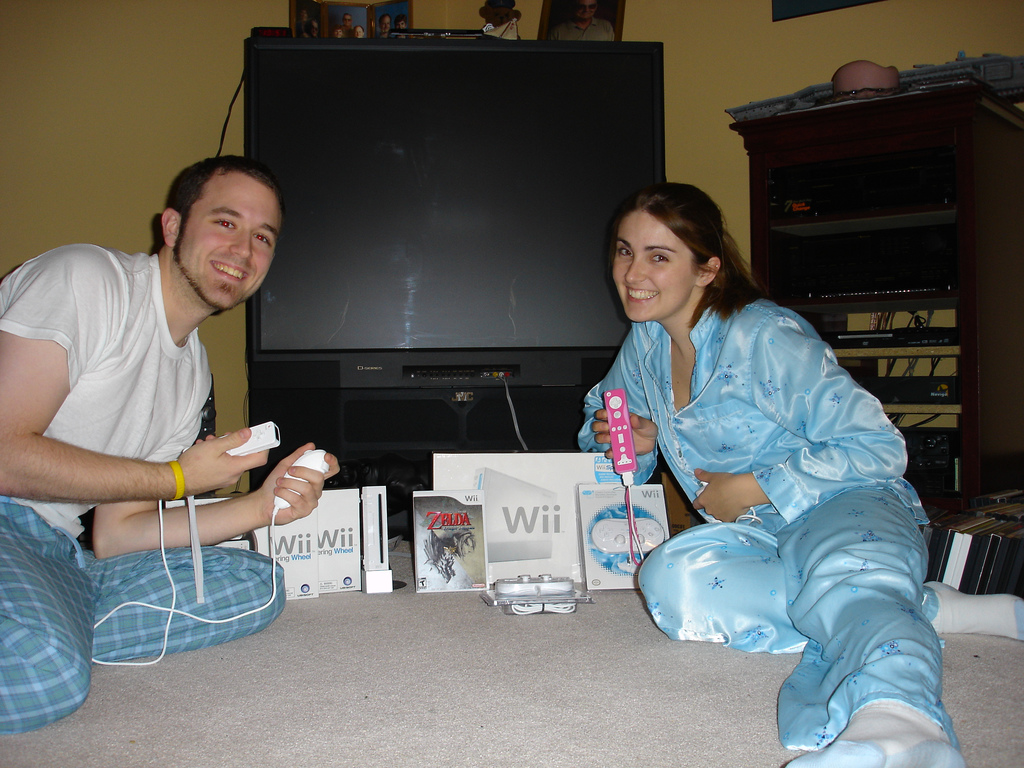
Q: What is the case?
A: Zelda game.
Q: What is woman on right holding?
A: Pink controller.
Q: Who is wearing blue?
A: Woman with pink controller.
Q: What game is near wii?
A: Zelda.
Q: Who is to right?
A: Woman in blue.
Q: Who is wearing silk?
A: Woman to the right.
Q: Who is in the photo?
A: Young couple.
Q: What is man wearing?
A: Blue flannel pants.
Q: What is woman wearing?
A: Blue 2 piece pajamas.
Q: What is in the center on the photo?
A: Zelda game.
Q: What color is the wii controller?
A: Pink and white.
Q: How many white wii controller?
A: Two.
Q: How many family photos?
A: Four.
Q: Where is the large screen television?
A: Behind the couple.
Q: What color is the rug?
A: Gray.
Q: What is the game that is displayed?
A: Zelda.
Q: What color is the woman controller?
A: Pink.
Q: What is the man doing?
A: Smiling.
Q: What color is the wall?
A: Yellow.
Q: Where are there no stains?
A: On the carpet.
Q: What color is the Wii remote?
A: Pink.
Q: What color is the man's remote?
A: White.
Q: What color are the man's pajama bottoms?
A: Blue plaid.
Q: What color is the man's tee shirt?
A: White.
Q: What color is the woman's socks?
A: White.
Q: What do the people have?
A: The complete Wii game.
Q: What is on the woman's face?
A: A big smile.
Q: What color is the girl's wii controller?
A: Pink.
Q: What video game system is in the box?
A: Wii.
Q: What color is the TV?
A: Black.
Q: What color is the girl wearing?
A: Blue.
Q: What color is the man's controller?
A: White.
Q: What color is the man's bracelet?
A: Yellow.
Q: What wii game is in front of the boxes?
A: Zelda.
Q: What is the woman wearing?
A: Pajamas.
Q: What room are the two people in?
A: The living room.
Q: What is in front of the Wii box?
A: Video games.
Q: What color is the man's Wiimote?
A: White.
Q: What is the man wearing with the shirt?
A: Pajamas.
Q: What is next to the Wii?
A: Accessories.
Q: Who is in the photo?
A: A happy couple.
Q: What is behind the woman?
A: A stereo cabinet.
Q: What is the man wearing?
A: Pajama pants.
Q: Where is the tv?
A: Above the WIi.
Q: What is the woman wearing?
A: Blue pajamas.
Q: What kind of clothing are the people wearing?
A: Pajamas.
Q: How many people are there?
A: 2.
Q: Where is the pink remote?
A: Woman's right hand.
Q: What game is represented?
A: Wii.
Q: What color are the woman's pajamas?
A: Blue.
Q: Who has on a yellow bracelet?
A: Man on the left.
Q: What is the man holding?
A: Game controller.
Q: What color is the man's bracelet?
A: Yellow.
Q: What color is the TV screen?
A: Black.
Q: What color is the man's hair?
A: Brown.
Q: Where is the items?
A: Top of television.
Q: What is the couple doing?
A: Posing with will console.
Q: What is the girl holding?
A: Wii remote.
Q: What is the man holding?
A: Will game pad.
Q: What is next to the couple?
A: Will console.